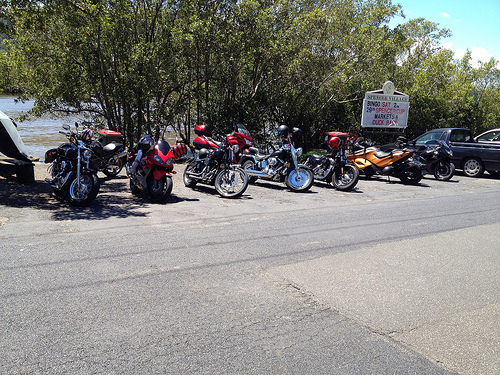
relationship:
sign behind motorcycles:
[357, 76, 413, 132] [36, 107, 462, 210]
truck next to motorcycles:
[420, 119, 500, 176] [36, 107, 462, 210]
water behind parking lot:
[4, 87, 103, 153] [36, 107, 462, 210]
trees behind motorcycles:
[6, 1, 492, 128] [36, 107, 462, 210]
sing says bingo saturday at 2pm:
[357, 76, 413, 132] [364, 97, 406, 115]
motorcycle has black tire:
[177, 113, 256, 203] [212, 163, 252, 200]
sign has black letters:
[357, 76, 413, 132] [365, 96, 405, 109]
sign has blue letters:
[357, 76, 413, 132] [371, 111, 402, 122]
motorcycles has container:
[44, 124, 121, 210] [28, 158, 55, 183]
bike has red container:
[177, 113, 256, 203] [189, 119, 220, 138]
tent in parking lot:
[3, 104, 42, 192] [7, 158, 467, 241]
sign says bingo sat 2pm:
[357, 76, 413, 132] [364, 97, 406, 115]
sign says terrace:
[357, 76, 413, 132] [365, 96, 405, 109]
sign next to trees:
[357, 76, 413, 132] [6, 1, 492, 128]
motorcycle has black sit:
[350, 135, 430, 187] [373, 146, 401, 158]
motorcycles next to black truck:
[36, 107, 462, 210] [420, 119, 500, 176]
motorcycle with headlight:
[235, 114, 319, 197] [291, 143, 306, 158]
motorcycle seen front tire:
[177, 113, 256, 203] [212, 163, 252, 200]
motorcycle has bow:
[120, 108, 176, 200] [126, 122, 164, 145]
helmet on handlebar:
[325, 132, 346, 155] [334, 133, 346, 143]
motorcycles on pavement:
[36, 107, 462, 210] [0, 162, 500, 375]